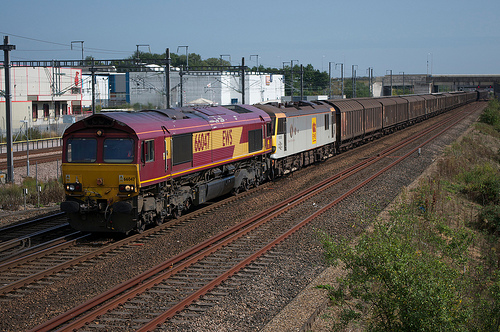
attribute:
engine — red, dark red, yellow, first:
[59, 105, 276, 233]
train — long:
[54, 84, 495, 235]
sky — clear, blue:
[1, 6, 498, 78]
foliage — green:
[324, 97, 499, 330]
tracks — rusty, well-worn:
[38, 100, 482, 330]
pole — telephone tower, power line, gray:
[4, 37, 19, 185]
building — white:
[1, 67, 289, 148]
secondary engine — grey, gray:
[263, 101, 342, 173]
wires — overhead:
[7, 37, 422, 81]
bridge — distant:
[433, 75, 498, 87]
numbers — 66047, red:
[192, 130, 211, 154]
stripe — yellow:
[140, 115, 276, 136]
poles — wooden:
[5, 39, 407, 186]